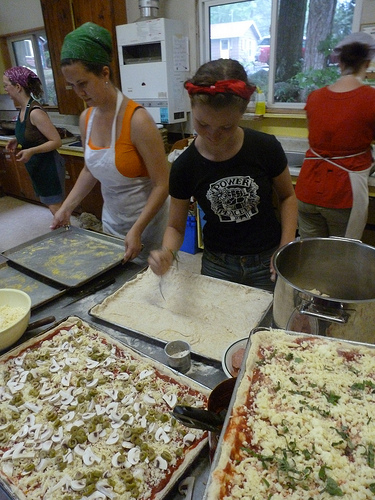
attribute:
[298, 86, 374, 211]
top — red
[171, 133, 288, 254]
t-shirt — black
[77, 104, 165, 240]
apron — white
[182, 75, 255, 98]
headband — red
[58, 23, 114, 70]
scarf — green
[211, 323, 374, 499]
pizza — raw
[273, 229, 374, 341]
pot — large, steel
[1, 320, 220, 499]
pizza — large, raw, rectangular